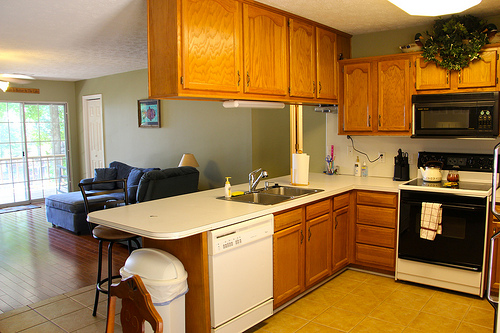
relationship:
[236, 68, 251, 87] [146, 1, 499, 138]
handles on front of cabinets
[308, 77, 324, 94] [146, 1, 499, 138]
handles on front of cabinets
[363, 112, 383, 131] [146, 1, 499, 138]
handles on front of cabinets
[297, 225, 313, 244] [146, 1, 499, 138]
handles on front of cabinets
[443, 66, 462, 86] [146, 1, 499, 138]
handles on front of cabinets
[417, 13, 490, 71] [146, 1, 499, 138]
plant in top of cabinets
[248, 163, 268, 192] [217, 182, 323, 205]
faucet over sink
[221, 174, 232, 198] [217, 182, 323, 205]
soap bottle on top of sink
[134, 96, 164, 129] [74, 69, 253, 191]
picture hanging on wall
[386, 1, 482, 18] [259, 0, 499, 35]
light mounted on ceiling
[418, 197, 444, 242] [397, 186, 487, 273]
dish towel hanging from oven door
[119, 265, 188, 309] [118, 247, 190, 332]
bag inside of trashcan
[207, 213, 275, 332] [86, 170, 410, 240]
dishwasher underneath counter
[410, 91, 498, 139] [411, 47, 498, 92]
microwave mounted under cabinet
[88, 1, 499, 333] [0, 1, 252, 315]
kitchen ext to livig room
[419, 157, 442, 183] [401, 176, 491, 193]
tea kettle o top of stove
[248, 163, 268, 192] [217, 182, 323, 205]
faucet o back of sink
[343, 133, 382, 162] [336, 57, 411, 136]
cord hanging from cabinet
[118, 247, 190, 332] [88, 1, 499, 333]
trashcan ide of kitchen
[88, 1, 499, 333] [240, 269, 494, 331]
kitchen has floor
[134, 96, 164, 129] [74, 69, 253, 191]
picture hanging o wall